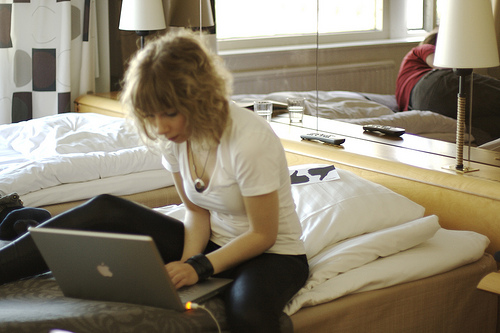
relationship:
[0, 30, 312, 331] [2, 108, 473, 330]
girl on bed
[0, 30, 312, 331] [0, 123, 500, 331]
girl on bed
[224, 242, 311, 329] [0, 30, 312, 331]
leg on girl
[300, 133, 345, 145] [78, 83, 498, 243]
remote on wooden ledge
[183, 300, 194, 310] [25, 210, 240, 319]
light on laptop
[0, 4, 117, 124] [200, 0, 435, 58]
curtain on window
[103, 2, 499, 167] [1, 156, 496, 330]
mirror behind bed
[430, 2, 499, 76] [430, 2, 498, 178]
shade on lamp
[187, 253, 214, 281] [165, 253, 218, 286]
leather on wrist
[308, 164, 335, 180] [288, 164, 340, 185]
hand on brochure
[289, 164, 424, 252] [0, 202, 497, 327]
pillow on bed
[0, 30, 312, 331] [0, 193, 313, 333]
girl in black pants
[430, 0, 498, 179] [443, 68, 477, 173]
lamp on lamp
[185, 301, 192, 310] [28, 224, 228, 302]
light on laptop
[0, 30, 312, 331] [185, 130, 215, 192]
girl wearing necklace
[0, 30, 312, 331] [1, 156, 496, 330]
girl on bed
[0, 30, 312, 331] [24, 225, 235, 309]
girl using computer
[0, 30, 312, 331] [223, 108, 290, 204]
girl wearing shirt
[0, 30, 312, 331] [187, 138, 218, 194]
girl wearing necklace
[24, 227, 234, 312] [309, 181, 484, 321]
computer on bed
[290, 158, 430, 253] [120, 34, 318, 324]
pillow behind girl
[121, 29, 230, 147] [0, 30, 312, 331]
curly hair on girl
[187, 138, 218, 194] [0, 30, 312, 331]
necklace on girl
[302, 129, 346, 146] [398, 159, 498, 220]
remote on ledge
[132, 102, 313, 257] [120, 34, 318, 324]
shirt on girl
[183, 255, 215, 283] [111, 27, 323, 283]
leather on girl